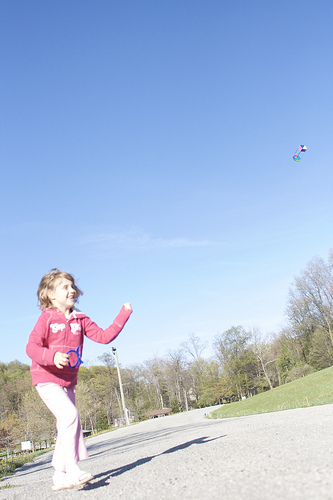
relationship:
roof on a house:
[148, 409, 170, 417] [145, 407, 172, 420]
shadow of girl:
[85, 433, 226, 487] [27, 268, 134, 493]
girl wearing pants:
[27, 268, 134, 493] [33, 384, 92, 470]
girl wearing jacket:
[27, 268, 134, 493] [25, 307, 134, 386]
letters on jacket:
[48, 321, 82, 335] [25, 307, 134, 386]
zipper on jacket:
[61, 317, 71, 344] [25, 307, 134, 386]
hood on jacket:
[70, 309, 92, 321] [25, 307, 134, 386]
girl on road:
[27, 268, 134, 493] [0, 404, 333, 499]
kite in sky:
[292, 145, 308, 161] [1, 1, 333, 363]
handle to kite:
[66, 345, 84, 370] [292, 145, 308, 161]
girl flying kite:
[27, 268, 134, 493] [292, 145, 308, 161]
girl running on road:
[27, 268, 134, 493] [0, 404, 333, 499]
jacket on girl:
[25, 307, 134, 386] [27, 268, 134, 493]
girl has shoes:
[27, 268, 134, 493] [49, 468, 94, 492]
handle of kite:
[66, 345, 84, 370] [292, 145, 308, 161]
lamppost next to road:
[111, 343, 132, 427] [0, 404, 333, 499]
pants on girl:
[33, 384, 92, 470] [27, 268, 134, 493]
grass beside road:
[203, 366, 332, 419] [0, 404, 333, 499]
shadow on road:
[85, 433, 226, 487] [0, 404, 333, 499]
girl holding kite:
[27, 268, 134, 493] [292, 145, 308, 161]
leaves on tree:
[229, 353, 253, 372] [229, 348, 261, 400]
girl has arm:
[27, 268, 134, 493] [83, 301, 138, 346]